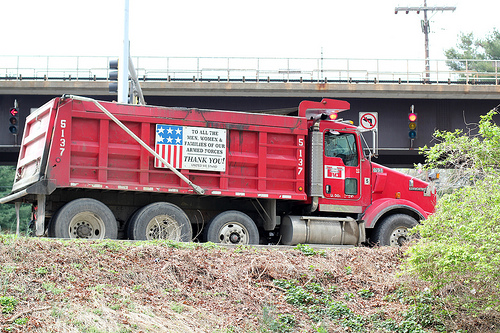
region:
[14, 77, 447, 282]
A red truck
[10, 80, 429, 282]
A red dump truck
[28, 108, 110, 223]
white numbers on a red truck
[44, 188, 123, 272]
The rear tire on a red truck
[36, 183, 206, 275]
two tires on a truck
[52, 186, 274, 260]
three tires on a truck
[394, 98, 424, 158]
a traffic signal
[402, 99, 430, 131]
A red light on a traffic signal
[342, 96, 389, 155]
A no left turn sign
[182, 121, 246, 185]
black letters on a white sign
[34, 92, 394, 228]
this is a lorry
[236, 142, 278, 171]
the lorry is red in color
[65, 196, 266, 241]
these are the wheels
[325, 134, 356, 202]
this is the door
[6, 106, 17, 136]
this is a traffic light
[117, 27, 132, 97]
this is a pole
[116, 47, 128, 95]
the pole is white in color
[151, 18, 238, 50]
this is the sky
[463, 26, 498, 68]
this is a tree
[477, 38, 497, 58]
the tree has green leaves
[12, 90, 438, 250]
the dump truck is empty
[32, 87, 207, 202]
the dump truck has a canvas to cover the load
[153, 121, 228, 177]
a sign is on the side of the truck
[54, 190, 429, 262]
the dump truck has wheels underneath in the back and front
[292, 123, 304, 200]
a number is on the side of the truck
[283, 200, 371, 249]
a diesel tank is near the door of the vehicle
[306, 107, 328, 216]
an exhaust system is on the side of the truck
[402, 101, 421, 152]
the traffic signal is red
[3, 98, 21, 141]
the traffic turning signal is red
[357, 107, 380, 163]
a no left turn sign near the traffic signals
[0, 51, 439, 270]
a large red dump truck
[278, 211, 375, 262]
a silver oil drum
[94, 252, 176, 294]
brown dead grass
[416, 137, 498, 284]
a bright green shrub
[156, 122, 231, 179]
a company sign on the side of the truck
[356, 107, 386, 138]
a sign with a black arrow and red circle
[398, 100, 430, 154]
a traffic light signaling on red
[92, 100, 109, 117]
a metal support bar on the truck side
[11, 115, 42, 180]
the red lift door on the back of the truck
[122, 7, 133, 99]
a white metal support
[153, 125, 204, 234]
Flag on side of truck.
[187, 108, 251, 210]
White sign with black writing.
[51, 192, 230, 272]
Black tires on truck.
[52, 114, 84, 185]
5137 on side of truck.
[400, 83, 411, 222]
Traffic light is on red.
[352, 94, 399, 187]
Arrow on white sign.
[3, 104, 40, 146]
Red arrow light up on sign.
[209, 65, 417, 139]
Truck near bridge.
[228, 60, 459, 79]
Railing along side of bridge.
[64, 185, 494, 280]
Truck is near side of road.